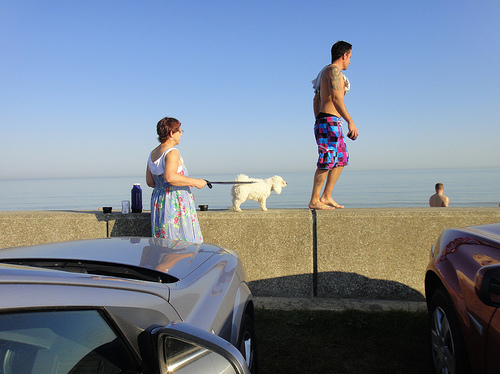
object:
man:
[308, 40, 359, 209]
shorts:
[314, 116, 350, 170]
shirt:
[311, 63, 351, 95]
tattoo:
[329, 66, 341, 91]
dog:
[231, 173, 287, 211]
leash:
[203, 179, 256, 189]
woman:
[145, 116, 207, 243]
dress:
[148, 147, 203, 243]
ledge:
[195, 209, 313, 295]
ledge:
[314, 207, 500, 300]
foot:
[308, 201, 335, 210]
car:
[424, 223, 500, 373]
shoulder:
[327, 66, 345, 91]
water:
[0, 166, 500, 212]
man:
[429, 182, 450, 207]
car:
[0, 236, 254, 374]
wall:
[0, 207, 500, 301]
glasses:
[180, 130, 185, 135]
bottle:
[131, 183, 143, 213]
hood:
[0, 235, 222, 283]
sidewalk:
[253, 295, 428, 358]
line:
[252, 297, 428, 312]